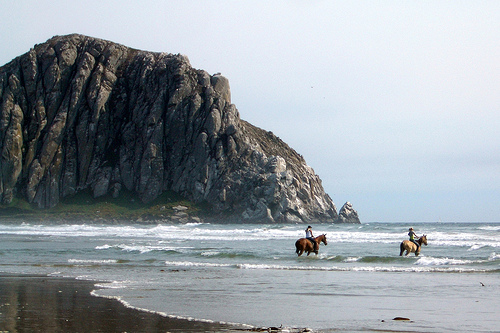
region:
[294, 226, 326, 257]
rider on a horse in the ocean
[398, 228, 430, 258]
rider on a horse in the ocean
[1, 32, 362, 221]
rocky cliffs next to ocean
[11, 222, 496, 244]
waves crashing in the ocean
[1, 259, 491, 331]
waves washing on the shore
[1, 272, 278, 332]
wet sand on the shore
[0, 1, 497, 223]
hazy sky above the ocean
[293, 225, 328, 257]
rider on a horse standing in ocean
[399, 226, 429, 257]
rider on a horse standing in ocean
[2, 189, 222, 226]
grassy hill beside cliffs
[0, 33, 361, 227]
A mountain in the distance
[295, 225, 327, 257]
A person on a horse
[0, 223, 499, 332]
Water with white waves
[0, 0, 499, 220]
A blue sky above mountain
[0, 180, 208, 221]
green grass below mountian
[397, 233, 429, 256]
A light brown horse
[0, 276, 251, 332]
Wet sand on a beach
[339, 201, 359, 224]
A triangular shaped rock in the distance.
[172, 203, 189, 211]
A small rock near mountain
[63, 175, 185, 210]
Shadow of mountain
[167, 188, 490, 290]
a body of water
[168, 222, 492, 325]
a body of wavy water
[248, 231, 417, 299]
a body of water with waves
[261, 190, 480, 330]
horses walking in the water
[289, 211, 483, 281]
people sitting on a horse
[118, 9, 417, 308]
large rocks in the water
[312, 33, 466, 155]
a cloudy sky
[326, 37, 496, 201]
a sky that is cloudy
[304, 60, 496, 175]
a blue sky that is cloudy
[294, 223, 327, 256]
A horse being ridden into the water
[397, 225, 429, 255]
A brown horse being ridden into the water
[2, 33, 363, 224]
A large, mountainous rock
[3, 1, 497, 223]
A grayish sky overhead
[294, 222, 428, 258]
Two brown horses being ridden into the water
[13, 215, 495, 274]
Waves crashing down onto the water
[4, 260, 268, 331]
Water washing onto the shore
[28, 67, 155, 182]
The rocky side of a hill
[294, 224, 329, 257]
A man on a horse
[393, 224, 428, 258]
A woman on a brown horse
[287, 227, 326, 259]
brown horse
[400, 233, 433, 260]
horse on beach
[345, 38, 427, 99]
white clouds in blue sky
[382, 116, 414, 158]
white clouds in blue sky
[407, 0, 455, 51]
white clouds in blue sky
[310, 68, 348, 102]
white clouds in blue sky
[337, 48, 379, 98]
white clouds in blue sky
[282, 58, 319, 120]
white clouds in blue sky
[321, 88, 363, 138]
white clouds in blue sky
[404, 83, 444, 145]
white clouds in blue sky